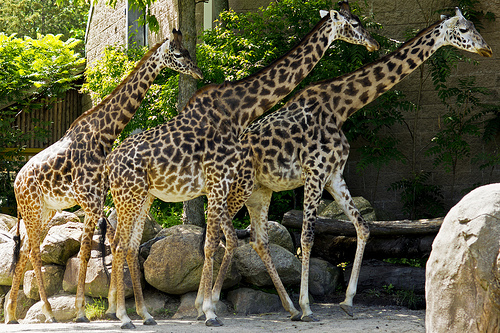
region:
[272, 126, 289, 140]
brown spot on giraffe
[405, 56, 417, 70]
brown spot on giraffe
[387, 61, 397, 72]
brown spot on giraffe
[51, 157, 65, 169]
brown spot on giraffe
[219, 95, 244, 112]
brown spot on giraffe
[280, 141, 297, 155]
brown spot on giraffe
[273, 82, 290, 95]
brown spot on giraffe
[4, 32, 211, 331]
last giraffe in a line of giraffes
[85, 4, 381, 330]
middle giraffe in a line of giraffes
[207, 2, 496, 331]
first giraffe in a line of giraffes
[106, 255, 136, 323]
leg of the giraffe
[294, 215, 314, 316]
leg of the giraffe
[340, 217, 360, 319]
leg of the giraffe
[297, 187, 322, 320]
leg of the giraffe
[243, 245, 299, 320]
leg of the giraffe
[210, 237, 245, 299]
leg of the giraffe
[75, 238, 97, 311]
leg of the giraffe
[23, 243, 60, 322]
leg of the giraffe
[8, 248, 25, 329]
leg of the giraffe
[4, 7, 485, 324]
three giraffes in tandem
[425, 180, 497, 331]
a rounded boulder on the right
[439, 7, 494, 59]
the head of the lead giraffe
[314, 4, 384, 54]
the head of the second giraffe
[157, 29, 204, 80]
the head of the third giraffe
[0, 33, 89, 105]
sunlight on the top of trees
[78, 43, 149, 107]
mall tree in front of a wall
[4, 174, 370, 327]
twelve legs of giraffes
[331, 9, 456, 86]
the mane of a giraffe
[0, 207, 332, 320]
a stack of large rocks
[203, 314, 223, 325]
The giraffe hoof is black.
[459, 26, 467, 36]
The giraffe eye is black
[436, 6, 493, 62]
The giraffes head is brown and white.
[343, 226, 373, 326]
The giraffes leg is white and brown.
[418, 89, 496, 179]
The wall in the background is brown.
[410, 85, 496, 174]
The wall in the background is made of brick.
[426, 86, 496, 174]
The plants in front of the wall are green.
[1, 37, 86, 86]
The leaves in the background are green.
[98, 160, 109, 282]
The giraffes tail is long.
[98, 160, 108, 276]
The giraffes tail is brown, black and white.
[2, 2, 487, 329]
several giraffe at a zoo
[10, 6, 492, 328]
three giraffe at a zoo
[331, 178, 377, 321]
the leg of a giraffe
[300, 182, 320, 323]
the leg of a giraffe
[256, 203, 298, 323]
the leg of a giraffe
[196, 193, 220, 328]
the leg of a giraffe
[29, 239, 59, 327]
the leg of a giraffe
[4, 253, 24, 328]
the leg of a giraffe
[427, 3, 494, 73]
the head of a giraffe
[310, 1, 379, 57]
the head of a giraffe